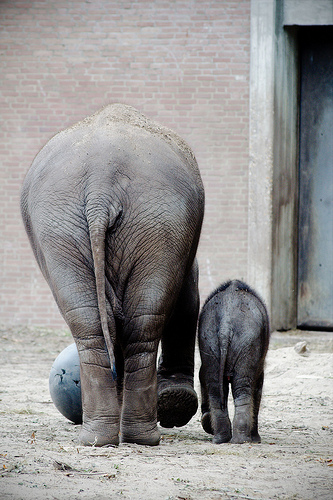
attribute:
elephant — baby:
[195, 278, 270, 443]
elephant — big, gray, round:
[19, 99, 208, 447]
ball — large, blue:
[49, 341, 118, 422]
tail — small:
[216, 320, 231, 408]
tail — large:
[83, 195, 122, 376]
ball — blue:
[49, 342, 84, 421]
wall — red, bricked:
[7, 2, 251, 328]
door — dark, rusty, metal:
[295, 29, 331, 328]